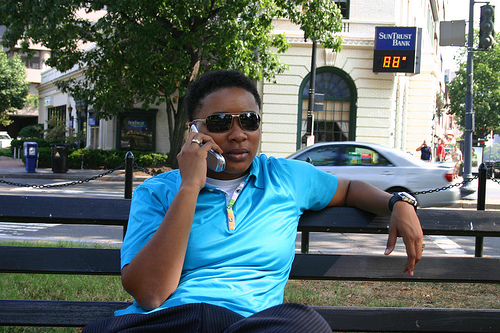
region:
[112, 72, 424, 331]
a woman sitting on a bench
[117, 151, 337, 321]
woman wearing a bright blue shirt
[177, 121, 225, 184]
woman talking on a silvery phone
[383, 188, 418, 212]
a black watch on woman's wrist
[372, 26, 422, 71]
a temperature display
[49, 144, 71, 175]
a black garbage can on a sidewalk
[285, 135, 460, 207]
a gray car driving on the street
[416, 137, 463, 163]
people walking on a sidewalk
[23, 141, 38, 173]
a blue mailbox on a sidewalk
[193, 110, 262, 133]
a woman wearing sunglasses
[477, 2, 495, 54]
Rear of traffic light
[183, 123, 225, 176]
Silver flip phone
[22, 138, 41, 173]
Dark blue newspaper box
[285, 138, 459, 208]
Silver four door sedan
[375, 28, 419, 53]
SunTrust Bank sign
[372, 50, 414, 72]
Temperature sign showing 88 degrees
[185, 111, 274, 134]
Silver-framed aviator sunglasses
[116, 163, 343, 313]
Shiny light blue polo shirt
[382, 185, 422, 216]
Wrist watch with black band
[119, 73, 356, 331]
African-American man talking on the phone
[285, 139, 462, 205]
Car on the street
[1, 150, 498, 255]
Metal chain on the poles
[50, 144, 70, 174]
Garbage can on the sidewalk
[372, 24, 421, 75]
Sign on the building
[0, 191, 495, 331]
Bench on the sidewalk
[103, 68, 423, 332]
Man sitting on the bench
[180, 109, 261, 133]
Sunglasses on the man's face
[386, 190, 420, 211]
Watch on the man's wrist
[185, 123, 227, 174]
Cellphone in the man's hand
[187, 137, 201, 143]
Ring on the man's finger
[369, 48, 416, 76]
a digital temperature display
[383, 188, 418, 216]
a watch with a black wristband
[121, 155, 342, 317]
a light blue polo shirt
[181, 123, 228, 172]
a silver flip phone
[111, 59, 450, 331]
a person talking on the phone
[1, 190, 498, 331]
a dark wood bench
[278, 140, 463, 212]
a moving silver sedan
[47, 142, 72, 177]
a black metal trash can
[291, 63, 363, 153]
a large window with green frame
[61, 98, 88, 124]
a pair of porch lights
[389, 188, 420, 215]
A black and silver wrist watch.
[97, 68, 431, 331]
A person sitting on a bench while talking on a cellphone.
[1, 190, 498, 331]
A bench.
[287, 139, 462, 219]
A silver four-door car.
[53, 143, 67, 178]
A black trashcan.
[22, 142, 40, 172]
A blue magazine stand.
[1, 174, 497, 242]
The road.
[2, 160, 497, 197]
A black chain.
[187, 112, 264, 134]
Black sunglasses.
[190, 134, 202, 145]
A silver ring.